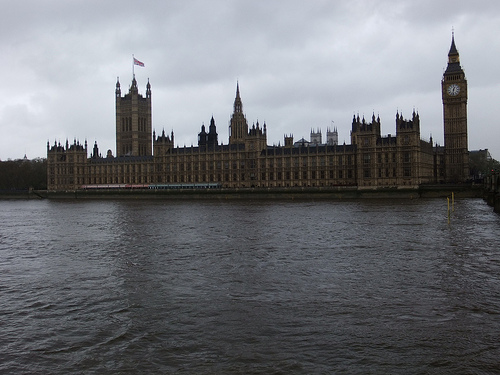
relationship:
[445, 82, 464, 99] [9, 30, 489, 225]
clock on building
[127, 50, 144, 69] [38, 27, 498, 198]
flag at top of building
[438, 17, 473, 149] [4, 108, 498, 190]
tower at end of building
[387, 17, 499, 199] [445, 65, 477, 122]
tower with clock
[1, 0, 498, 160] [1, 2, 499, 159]
clouds in sky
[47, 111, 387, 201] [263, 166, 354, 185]
building with windows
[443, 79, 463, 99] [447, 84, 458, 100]
clock with numbers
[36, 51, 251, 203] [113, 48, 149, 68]
castle with flag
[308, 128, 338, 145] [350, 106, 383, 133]
towers with spires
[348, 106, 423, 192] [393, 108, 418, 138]
towers with spires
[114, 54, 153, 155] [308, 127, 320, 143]
towers with spires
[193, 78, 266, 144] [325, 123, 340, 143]
towers with spires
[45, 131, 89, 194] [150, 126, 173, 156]
towers with spires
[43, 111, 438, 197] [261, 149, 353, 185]
building has windows